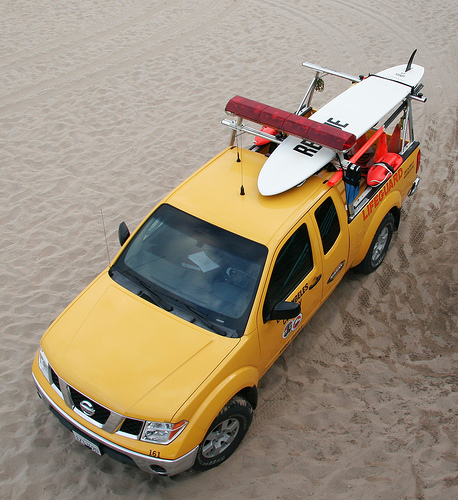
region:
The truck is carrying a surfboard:
[8, 33, 442, 478]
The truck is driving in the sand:
[23, 43, 451, 496]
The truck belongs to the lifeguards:
[5, 40, 439, 498]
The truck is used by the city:
[4, 39, 444, 497]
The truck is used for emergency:
[0, 47, 455, 492]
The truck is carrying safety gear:
[12, 47, 455, 479]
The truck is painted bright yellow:
[16, 43, 442, 497]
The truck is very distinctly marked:
[6, 61, 446, 485]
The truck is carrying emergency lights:
[8, 36, 451, 466]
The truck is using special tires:
[3, 43, 454, 498]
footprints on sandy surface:
[4, 2, 454, 492]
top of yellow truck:
[30, 48, 423, 480]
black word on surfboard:
[257, 48, 425, 196]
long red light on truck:
[225, 93, 355, 151]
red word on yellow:
[361, 169, 404, 220]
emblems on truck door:
[276, 275, 319, 337]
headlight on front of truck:
[141, 421, 172, 444]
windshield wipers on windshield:
[121, 267, 225, 337]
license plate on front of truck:
[71, 428, 100, 456]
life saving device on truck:
[365, 153, 404, 187]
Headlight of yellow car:
[135, 416, 175, 443]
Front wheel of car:
[188, 394, 257, 472]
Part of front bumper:
[108, 441, 200, 479]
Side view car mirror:
[254, 297, 302, 326]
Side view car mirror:
[109, 218, 130, 239]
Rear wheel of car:
[354, 201, 402, 273]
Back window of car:
[309, 193, 342, 254]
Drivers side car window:
[260, 223, 314, 322]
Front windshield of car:
[115, 201, 265, 326]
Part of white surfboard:
[253, 151, 316, 198]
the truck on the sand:
[33, 78, 423, 479]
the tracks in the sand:
[383, 199, 447, 374]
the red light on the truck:
[213, 91, 358, 155]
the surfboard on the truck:
[241, 46, 430, 213]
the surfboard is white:
[247, 49, 426, 200]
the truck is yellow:
[26, 85, 426, 465]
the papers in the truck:
[177, 243, 220, 275]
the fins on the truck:
[341, 161, 365, 208]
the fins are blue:
[344, 160, 362, 212]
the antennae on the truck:
[225, 114, 256, 198]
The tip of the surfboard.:
[256, 153, 294, 199]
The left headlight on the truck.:
[33, 351, 54, 379]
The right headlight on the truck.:
[143, 420, 167, 438]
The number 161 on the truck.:
[148, 449, 159, 456]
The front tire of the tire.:
[196, 407, 253, 463]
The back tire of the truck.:
[373, 217, 391, 269]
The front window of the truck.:
[115, 204, 264, 336]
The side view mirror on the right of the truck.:
[274, 299, 302, 319]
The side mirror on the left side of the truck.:
[109, 219, 129, 244]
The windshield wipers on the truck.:
[121, 271, 232, 345]